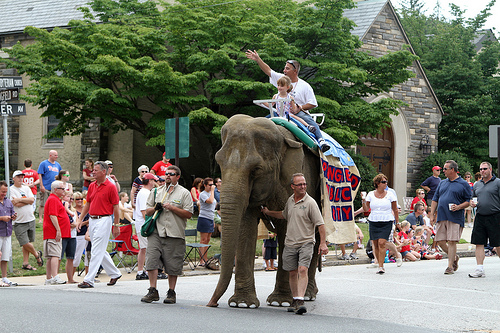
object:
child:
[260, 76, 317, 133]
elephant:
[205, 113, 363, 309]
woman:
[361, 173, 403, 274]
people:
[429, 159, 473, 274]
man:
[244, 49, 331, 154]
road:
[0, 244, 499, 333]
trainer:
[141, 165, 195, 305]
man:
[8, 169, 43, 271]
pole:
[2, 118, 15, 200]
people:
[467, 161, 499, 278]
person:
[260, 172, 329, 313]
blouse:
[365, 189, 398, 222]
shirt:
[281, 191, 325, 249]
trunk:
[205, 169, 253, 308]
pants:
[83, 215, 124, 288]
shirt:
[86, 178, 120, 216]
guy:
[75, 161, 121, 289]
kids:
[395, 220, 422, 261]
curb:
[256, 204, 274, 210]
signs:
[0, 102, 24, 117]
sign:
[317, 148, 362, 243]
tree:
[0, 0, 418, 180]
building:
[0, 0, 447, 216]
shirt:
[431, 176, 472, 228]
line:
[318, 291, 499, 314]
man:
[134, 173, 156, 280]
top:
[135, 187, 152, 233]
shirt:
[37, 159, 63, 190]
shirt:
[42, 192, 71, 240]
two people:
[245, 49, 331, 153]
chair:
[112, 224, 141, 273]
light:
[419, 136, 433, 155]